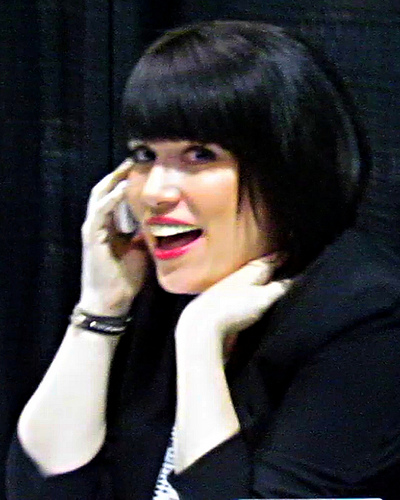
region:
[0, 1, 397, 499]
a black haired woman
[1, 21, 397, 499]
a woman talking on a cellphone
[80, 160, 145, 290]
a cellphone in the woman's right hand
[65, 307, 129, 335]
a black and silver wrist band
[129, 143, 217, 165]
a blue eyed woman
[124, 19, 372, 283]
black hair on the woman's head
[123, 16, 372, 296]
a bang cut hairstyle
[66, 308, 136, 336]
a black and silver band on the woman's right wrist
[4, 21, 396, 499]
a woman in a blue suit jacket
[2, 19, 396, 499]
a woman smiling while talking on the phone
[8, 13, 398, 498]
a woman holding a cell phone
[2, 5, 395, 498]
a woman looking at the camera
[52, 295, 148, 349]
a black and gray bracelet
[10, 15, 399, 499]
a person holding a phone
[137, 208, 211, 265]
red lipstick on lip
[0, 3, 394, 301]
a black background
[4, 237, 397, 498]
a black outfit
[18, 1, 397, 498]
a white woman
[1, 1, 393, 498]
a person who is smiling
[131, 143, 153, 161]
the brown eye of a woman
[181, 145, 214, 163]
the brown eye of a woman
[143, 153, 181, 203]
the nose of a face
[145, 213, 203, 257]
the mouth of a face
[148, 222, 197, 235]
the teeth of a face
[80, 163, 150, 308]
the hand holding a cell phone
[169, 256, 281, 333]
the hand of a woman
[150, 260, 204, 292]
the chin of a face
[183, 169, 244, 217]
the cheek of a face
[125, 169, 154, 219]
the cheek of a face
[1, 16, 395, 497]
A woman talking on a cellphone.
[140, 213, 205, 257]
Bright lipstick on a woman's mouth.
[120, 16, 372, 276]
A short dark haircut.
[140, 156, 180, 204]
A woman's nose.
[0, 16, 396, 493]
A woman in a dark jacket.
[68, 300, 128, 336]
An object on a woman's wrist.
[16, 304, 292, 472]
A woman's bare arms.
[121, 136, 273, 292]
A woman's face with makeup on it.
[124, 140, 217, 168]
A woman's eyes.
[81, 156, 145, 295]
A cellphone in a woman's hand.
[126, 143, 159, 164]
The left eye of the lady.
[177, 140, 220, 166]
The right eye of the lady.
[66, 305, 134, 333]
The bracelet on the lady's left wrist.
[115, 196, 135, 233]
The phone in the lady's hand.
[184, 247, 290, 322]
The lady's right hand.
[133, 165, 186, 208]
The nose of the lady.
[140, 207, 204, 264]
The lips of the lady.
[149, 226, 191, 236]
The teeth of the lady.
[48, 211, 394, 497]
The black jacket the lady is wearing.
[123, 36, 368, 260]
The lady's short black hair.